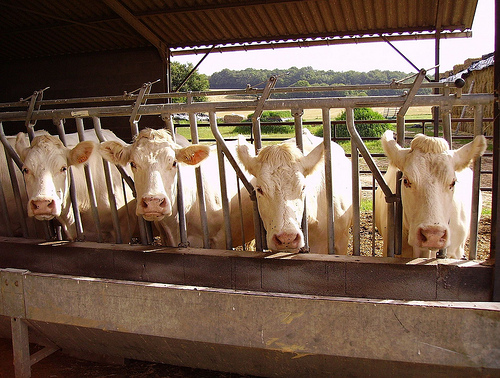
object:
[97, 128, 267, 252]
cow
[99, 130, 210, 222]
head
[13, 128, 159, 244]
cow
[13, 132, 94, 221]
head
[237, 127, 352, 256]
cow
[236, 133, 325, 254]
head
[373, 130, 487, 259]
cow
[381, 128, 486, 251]
head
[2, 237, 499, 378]
trough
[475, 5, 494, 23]
sun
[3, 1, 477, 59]
roof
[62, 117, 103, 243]
holes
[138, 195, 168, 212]
nose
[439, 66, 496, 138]
hay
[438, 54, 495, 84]
tarp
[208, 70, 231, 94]
forest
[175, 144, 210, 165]
ear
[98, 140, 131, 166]
ear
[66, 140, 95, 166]
ear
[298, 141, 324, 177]
ear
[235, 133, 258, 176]
ear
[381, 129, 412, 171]
ear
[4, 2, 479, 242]
barn